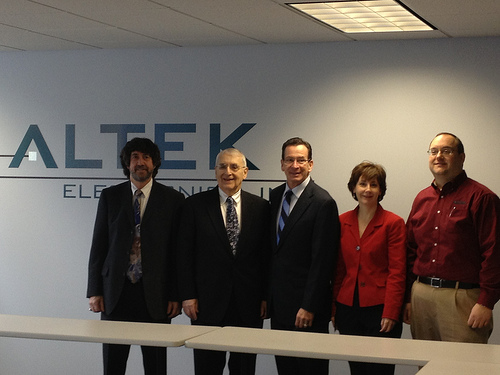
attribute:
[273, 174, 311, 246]
shirt — burgundy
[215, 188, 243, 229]
shirt — burgundy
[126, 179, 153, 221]
shirt — burgundy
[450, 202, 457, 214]
pen — ink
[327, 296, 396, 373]
pants — BLACK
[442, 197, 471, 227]
pocket — shirt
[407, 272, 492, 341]
pants — tan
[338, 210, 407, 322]
jacket — red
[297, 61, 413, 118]
wall — white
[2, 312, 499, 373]
white table — white  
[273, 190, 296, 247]
tie — blue striped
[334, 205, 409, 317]
jacket — red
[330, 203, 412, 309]
jacket — red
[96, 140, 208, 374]
man — is very dark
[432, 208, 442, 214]
button — white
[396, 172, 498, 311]
shirt — burgundy, red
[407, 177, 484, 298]
shirt — red  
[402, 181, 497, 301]
shirt — burgundy